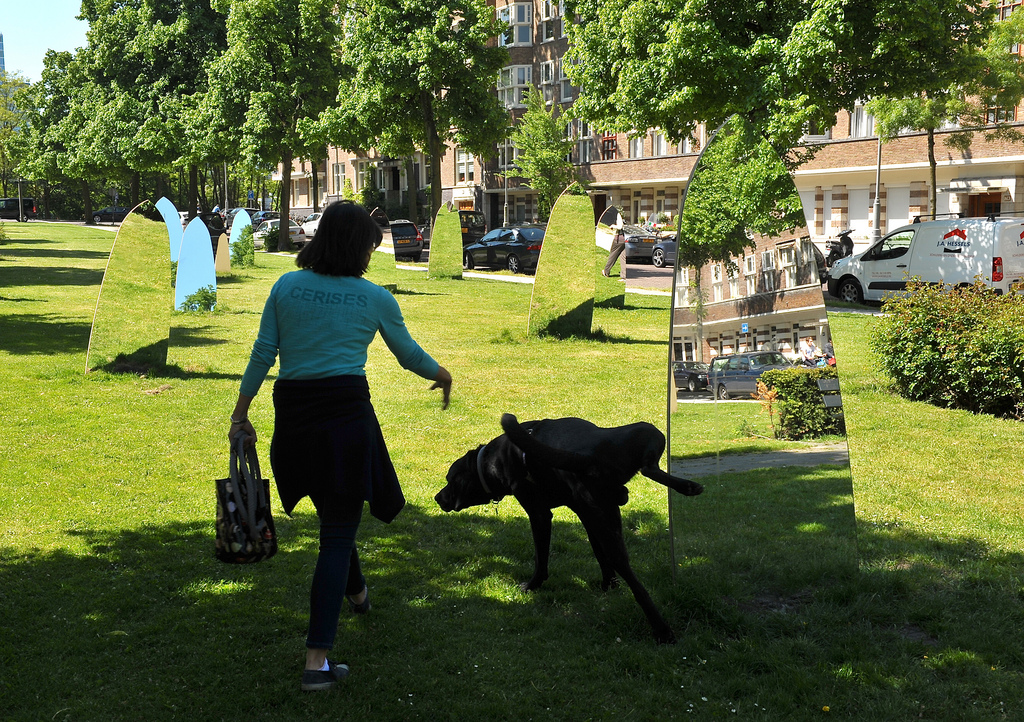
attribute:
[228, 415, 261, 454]
hand — woman's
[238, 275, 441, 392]
shirt — teal 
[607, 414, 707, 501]
leg — hind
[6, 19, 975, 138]
leaves — green 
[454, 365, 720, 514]
dog — using bathroom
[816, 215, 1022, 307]
van — white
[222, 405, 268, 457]
hand — woman's